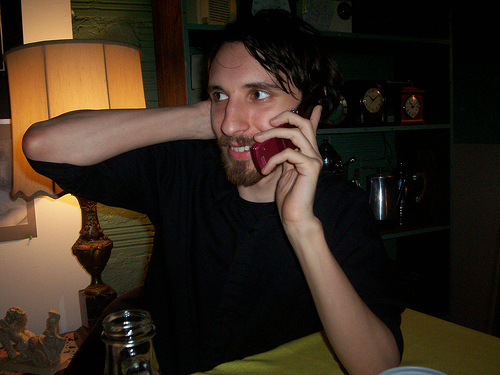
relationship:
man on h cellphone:
[19, 6, 404, 375] [249, 79, 329, 171]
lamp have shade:
[7, 38, 146, 334] [20, 49, 145, 188]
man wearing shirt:
[19, 6, 404, 375] [28, 134, 407, 371]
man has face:
[19, 6, 404, 375] [209, 41, 297, 190]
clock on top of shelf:
[345, 72, 394, 127] [153, 1, 459, 323]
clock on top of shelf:
[391, 82, 431, 125] [153, 1, 459, 323]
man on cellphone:
[19, 6, 404, 375] [249, 79, 329, 171]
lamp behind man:
[7, 38, 146, 334] [19, 6, 404, 375]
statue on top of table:
[5, 305, 72, 374] [0, 326, 94, 374]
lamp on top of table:
[7, 38, 146, 334] [0, 326, 94, 374]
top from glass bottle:
[103, 308, 153, 339] [96, 304, 164, 375]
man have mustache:
[19, 6, 404, 375] [215, 132, 255, 144]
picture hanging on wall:
[0, 1, 40, 247] [1, 8, 164, 340]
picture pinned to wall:
[0, 1, 40, 247] [1, 8, 164, 340]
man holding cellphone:
[19, 6, 404, 375] [249, 79, 329, 171]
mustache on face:
[215, 132, 255, 144] [209, 41, 297, 190]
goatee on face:
[218, 160, 258, 186] [209, 41, 297, 190]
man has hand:
[19, 6, 404, 375] [256, 104, 330, 217]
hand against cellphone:
[256, 104, 330, 217] [249, 79, 329, 171]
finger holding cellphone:
[270, 113, 321, 152] [249, 79, 329, 171]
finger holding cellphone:
[251, 125, 313, 162] [249, 79, 329, 171]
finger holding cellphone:
[261, 147, 311, 176] [249, 79, 329, 171]